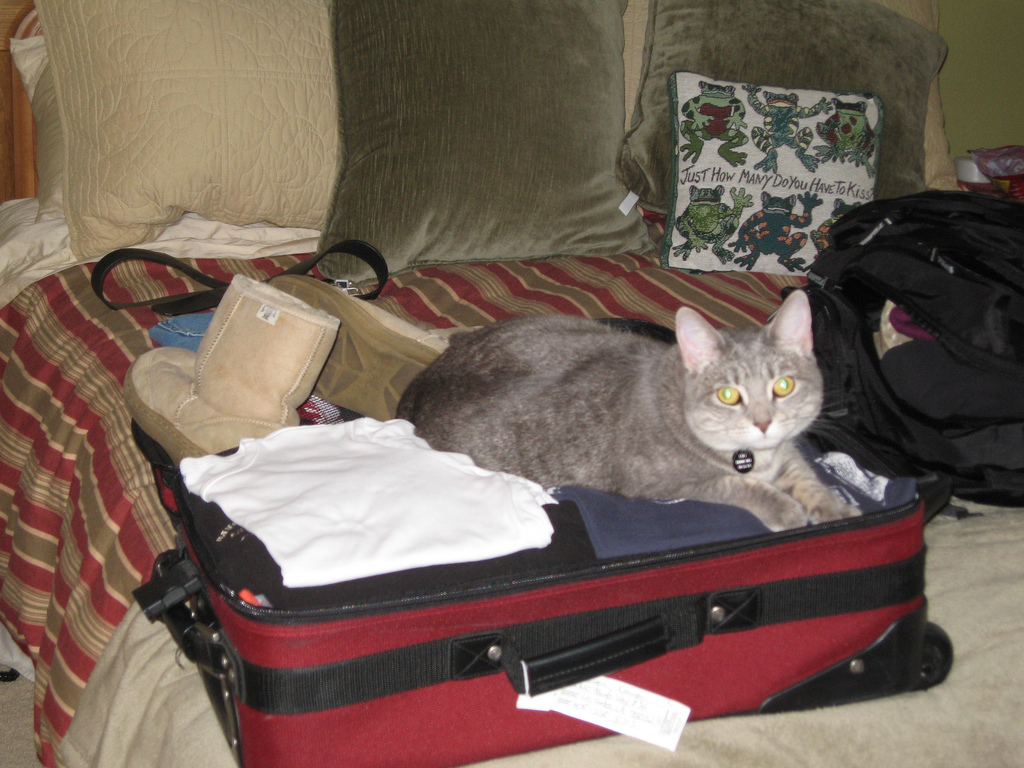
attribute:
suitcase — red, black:
[162, 451, 940, 763]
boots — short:
[125, 273, 354, 468]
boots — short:
[256, 255, 505, 430]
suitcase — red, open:
[128, 425, 956, 765]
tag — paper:
[515, 660, 693, 753]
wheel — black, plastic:
[898, 621, 955, 691]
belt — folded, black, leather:
[89, 237, 392, 311]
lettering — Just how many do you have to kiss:
[679, 165, 876, 205]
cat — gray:
[396, 284, 865, 531]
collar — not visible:
[696, 442, 803, 449]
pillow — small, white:
[660, 66, 885, 278]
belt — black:
[90, 243, 391, 317]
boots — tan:
[124, 271, 449, 462]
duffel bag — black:
[807, 183, 1022, 519]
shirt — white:
[180, 414, 561, 589]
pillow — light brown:
[33, 1, 342, 267]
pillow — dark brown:
[425, 206, 572, 278]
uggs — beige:
[186, 279, 347, 494]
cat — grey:
[607, 331, 802, 520]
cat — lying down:
[644, 404, 765, 543]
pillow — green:
[466, 63, 590, 282]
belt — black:
[127, 225, 221, 349]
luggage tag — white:
[523, 571, 660, 764]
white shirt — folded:
[408, 448, 530, 649]